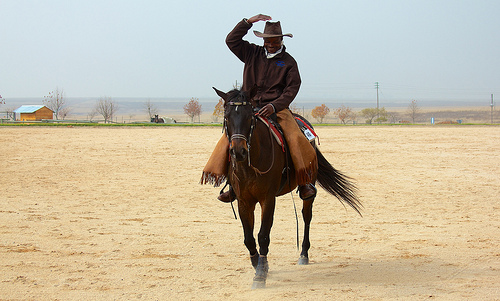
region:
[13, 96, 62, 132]
a wooden house with white roof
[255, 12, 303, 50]
man holding his hat on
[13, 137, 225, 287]
the field is full of sand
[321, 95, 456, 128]
trees in the grass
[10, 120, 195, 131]
grass along the dirt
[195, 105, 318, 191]
the man is wearing leather chaps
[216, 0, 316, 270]
man riding a horse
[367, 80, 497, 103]
power lines along the trees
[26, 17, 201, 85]
the sky is overcast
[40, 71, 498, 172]
dust in the air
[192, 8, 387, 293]
man riding a brown horse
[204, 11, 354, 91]
man in a cowboy hat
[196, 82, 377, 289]
brown horse carrying a man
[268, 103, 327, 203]
leather chaps with fringe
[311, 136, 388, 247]
dark brown horse tail waving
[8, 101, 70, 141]
yellow building with a white roof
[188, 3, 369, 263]
man in a horse's saddle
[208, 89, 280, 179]
horse head with reins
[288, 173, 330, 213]
man's foot in a stirrup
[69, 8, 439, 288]
man riding the horse in the sand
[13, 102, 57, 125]
house in the background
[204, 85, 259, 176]
horse's brown head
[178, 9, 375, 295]
man wearing brown jacket, brown hat, and tan chaps, riding a brown horse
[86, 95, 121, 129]
second tree from the left in the background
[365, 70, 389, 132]
tallest powerline in the background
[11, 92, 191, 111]
horizon to the left of the rider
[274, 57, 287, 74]
blue writing on man's jacket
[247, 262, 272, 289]
horse's front left hoof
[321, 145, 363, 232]
horse's brown tail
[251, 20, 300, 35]
man's brown hat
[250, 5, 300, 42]
a brown cowboy hat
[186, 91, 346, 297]
a brown horse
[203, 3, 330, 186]
a man riding a horse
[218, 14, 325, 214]
a man dressed like a cowboy riding a horse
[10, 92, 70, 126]
a yellow house with a yellow roof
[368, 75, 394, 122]
a telephone pole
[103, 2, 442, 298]
a horse running on dry sand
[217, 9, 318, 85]
a man trying to hold on to his cowboy hat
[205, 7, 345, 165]
a man siting on the saddle of a horse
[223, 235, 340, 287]
the dirty hoofs of a horse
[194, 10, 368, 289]
black cowboy on a horse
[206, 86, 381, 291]
brown horse carrying a rider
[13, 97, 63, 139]
small yellow house with a white roof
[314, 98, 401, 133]
trees along the property line turning orange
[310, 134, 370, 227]
waving tail behind a horse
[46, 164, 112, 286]
sandy terrain with footprints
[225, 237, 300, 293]
hooves of a brown horse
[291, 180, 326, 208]
foot in a stirrup